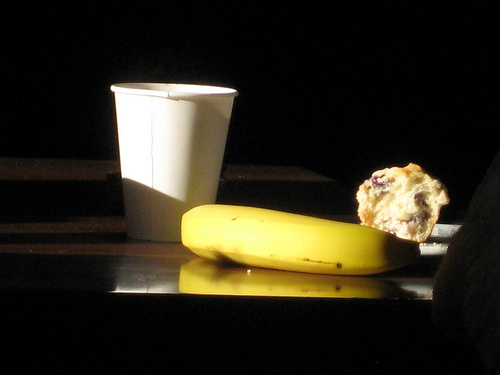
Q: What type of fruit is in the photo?
A: Banana.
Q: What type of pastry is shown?
A: Muffin.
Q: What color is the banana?
A: Yellow.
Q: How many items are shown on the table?
A: Three.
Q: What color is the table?
A: Brown.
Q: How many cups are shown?
A: One.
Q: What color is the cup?
A: White.